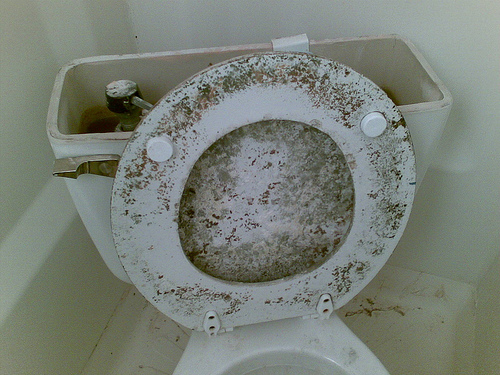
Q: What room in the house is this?
A: Bathroom.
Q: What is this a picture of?
A: Toilet.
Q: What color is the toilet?
A: White.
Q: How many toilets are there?
A: 1.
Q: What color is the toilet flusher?
A: Silver.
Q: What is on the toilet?
A: Dirt.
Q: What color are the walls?
A: White.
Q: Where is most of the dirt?
A: Toilet seat.